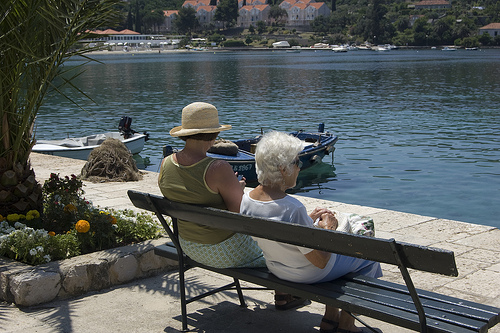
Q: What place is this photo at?
A: It is at the lake.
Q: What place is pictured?
A: It is a lake.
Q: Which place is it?
A: It is a lake.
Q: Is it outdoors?
A: Yes, it is outdoors.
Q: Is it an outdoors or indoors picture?
A: It is outdoors.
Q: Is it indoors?
A: No, it is outdoors.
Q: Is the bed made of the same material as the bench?
A: No, the bed is made of cement and the bench is made of wood.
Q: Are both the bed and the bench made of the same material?
A: No, the bed is made of cement and the bench is made of wood.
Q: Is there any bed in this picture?
A: Yes, there is a bed.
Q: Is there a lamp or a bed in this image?
A: Yes, there is a bed.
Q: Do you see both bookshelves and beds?
A: No, there is a bed but no bookshelves.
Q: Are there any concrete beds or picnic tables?
A: Yes, there is a concrete bed.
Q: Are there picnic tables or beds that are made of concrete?
A: Yes, the bed is made of concrete.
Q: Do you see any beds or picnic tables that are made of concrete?
A: Yes, the bed is made of concrete.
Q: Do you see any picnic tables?
A: No, there are no picnic tables.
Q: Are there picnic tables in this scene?
A: No, there are no picnic tables.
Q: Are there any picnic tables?
A: No, there are no picnic tables.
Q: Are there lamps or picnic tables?
A: No, there are no picnic tables or lamps.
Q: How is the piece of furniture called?
A: The piece of furniture is a bed.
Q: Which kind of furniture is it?
A: The piece of furniture is a bed.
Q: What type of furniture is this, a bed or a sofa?
A: That is a bed.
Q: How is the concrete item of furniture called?
A: The piece of furniture is a bed.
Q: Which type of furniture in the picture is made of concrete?
A: The furniture is a bed.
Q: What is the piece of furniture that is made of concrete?
A: The piece of furniture is a bed.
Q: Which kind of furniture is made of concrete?
A: The furniture is a bed.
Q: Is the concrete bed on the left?
A: Yes, the bed is on the left of the image.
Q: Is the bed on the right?
A: No, the bed is on the left of the image.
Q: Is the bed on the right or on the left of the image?
A: The bed is on the left of the image.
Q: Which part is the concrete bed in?
A: The bed is on the left of the image.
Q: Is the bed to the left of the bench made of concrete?
A: Yes, the bed is made of concrete.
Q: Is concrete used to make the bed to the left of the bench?
A: Yes, the bed is made of concrete.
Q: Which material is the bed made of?
A: The bed is made of cement.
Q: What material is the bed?
A: The bed is made of cement.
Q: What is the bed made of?
A: The bed is made of concrete.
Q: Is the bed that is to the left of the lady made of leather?
A: No, the bed is made of cement.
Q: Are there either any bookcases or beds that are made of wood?
A: No, there is a bed but it is made of concrete.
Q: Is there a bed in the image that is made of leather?
A: No, there is a bed but it is made of cement.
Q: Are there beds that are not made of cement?
A: No, there is a bed but it is made of cement.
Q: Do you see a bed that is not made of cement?
A: No, there is a bed but it is made of cement.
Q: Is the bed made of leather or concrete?
A: The bed is made of concrete.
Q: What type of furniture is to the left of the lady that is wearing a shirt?
A: The piece of furniture is a bed.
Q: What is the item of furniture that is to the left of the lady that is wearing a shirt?
A: The piece of furniture is a bed.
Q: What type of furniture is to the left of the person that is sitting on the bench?
A: The piece of furniture is a bed.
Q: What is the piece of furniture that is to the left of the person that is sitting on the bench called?
A: The piece of furniture is a bed.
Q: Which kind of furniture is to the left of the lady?
A: The piece of furniture is a bed.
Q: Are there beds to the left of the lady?
A: Yes, there is a bed to the left of the lady.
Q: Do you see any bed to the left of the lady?
A: Yes, there is a bed to the left of the lady.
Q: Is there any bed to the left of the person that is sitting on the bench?
A: Yes, there is a bed to the left of the lady.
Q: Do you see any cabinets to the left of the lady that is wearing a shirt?
A: No, there is a bed to the left of the lady.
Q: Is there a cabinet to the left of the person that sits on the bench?
A: No, there is a bed to the left of the lady.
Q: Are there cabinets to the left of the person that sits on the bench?
A: No, there is a bed to the left of the lady.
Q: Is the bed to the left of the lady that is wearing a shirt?
A: Yes, the bed is to the left of the lady.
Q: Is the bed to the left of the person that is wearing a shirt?
A: Yes, the bed is to the left of the lady.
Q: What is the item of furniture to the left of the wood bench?
A: The piece of furniture is a bed.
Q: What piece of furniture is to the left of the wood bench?
A: The piece of furniture is a bed.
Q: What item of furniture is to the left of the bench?
A: The piece of furniture is a bed.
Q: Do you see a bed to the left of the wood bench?
A: Yes, there is a bed to the left of the bench.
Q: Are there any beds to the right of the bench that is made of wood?
A: No, the bed is to the left of the bench.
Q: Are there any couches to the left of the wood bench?
A: No, there is a bed to the left of the bench.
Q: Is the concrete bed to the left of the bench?
A: Yes, the bed is to the left of the bench.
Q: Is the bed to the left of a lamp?
A: No, the bed is to the left of the bench.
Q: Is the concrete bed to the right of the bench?
A: No, the bed is to the left of the bench.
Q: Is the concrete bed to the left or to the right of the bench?
A: The bed is to the left of the bench.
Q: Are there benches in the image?
A: Yes, there is a bench.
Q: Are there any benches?
A: Yes, there is a bench.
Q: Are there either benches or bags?
A: Yes, there is a bench.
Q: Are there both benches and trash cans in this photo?
A: No, there is a bench but no trash cans.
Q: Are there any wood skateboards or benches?
A: Yes, there is a wood bench.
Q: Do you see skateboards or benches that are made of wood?
A: Yes, the bench is made of wood.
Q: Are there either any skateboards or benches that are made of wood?
A: Yes, the bench is made of wood.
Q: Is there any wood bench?
A: Yes, there is a bench that is made of wood.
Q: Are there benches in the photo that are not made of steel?
A: Yes, there is a bench that is made of wood.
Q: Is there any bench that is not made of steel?
A: Yes, there is a bench that is made of wood.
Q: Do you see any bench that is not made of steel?
A: Yes, there is a bench that is made of wood.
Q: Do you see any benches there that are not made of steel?
A: Yes, there is a bench that is made of wood.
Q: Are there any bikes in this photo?
A: No, there are no bikes.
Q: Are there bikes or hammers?
A: No, there are no bikes or hammers.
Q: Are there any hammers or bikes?
A: No, there are no bikes or hammers.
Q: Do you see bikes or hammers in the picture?
A: No, there are no bikes or hammers.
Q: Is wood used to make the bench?
A: Yes, the bench is made of wood.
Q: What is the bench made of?
A: The bench is made of wood.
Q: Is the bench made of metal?
A: No, the bench is made of wood.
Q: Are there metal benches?
A: No, there is a bench but it is made of wood.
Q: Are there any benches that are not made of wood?
A: No, there is a bench but it is made of wood.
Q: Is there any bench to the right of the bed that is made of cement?
A: Yes, there is a bench to the right of the bed.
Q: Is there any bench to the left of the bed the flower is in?
A: No, the bench is to the right of the bed.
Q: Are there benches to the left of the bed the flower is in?
A: No, the bench is to the right of the bed.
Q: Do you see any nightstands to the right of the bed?
A: No, there is a bench to the right of the bed.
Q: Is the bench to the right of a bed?
A: Yes, the bench is to the right of a bed.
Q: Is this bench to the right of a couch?
A: No, the bench is to the right of a bed.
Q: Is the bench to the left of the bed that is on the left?
A: No, the bench is to the right of the bed.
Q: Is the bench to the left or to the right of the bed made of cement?
A: The bench is to the right of the bed.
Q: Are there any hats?
A: Yes, there is a hat.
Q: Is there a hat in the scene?
A: Yes, there is a hat.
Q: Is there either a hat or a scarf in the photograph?
A: Yes, there is a hat.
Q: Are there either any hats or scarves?
A: Yes, there is a hat.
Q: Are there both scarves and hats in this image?
A: No, there is a hat but no scarves.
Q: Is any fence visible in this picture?
A: No, there are no fences.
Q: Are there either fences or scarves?
A: No, there are no fences or scarves.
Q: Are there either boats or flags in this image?
A: Yes, there is a boat.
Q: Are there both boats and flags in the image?
A: No, there is a boat but no flags.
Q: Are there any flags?
A: No, there are no flags.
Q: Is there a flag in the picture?
A: No, there are no flags.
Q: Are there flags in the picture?
A: No, there are no flags.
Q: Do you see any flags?
A: No, there are no flags.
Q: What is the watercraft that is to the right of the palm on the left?
A: The watercraft is a boat.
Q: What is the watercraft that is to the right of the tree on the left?
A: The watercraft is a boat.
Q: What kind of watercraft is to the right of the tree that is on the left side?
A: The watercraft is a boat.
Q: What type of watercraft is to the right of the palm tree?
A: The watercraft is a boat.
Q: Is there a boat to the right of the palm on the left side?
A: Yes, there is a boat to the right of the palm.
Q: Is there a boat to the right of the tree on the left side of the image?
A: Yes, there is a boat to the right of the palm.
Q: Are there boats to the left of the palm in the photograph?
A: No, the boat is to the right of the palm.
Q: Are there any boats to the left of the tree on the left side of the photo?
A: No, the boat is to the right of the palm.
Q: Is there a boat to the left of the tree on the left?
A: No, the boat is to the right of the palm.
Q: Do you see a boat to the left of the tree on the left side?
A: No, the boat is to the right of the palm.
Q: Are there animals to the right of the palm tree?
A: No, there is a boat to the right of the palm tree.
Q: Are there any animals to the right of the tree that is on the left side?
A: No, there is a boat to the right of the palm tree.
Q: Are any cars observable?
A: No, there are no cars.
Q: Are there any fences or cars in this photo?
A: No, there are no cars or fences.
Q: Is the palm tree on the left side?
A: Yes, the palm tree is on the left of the image.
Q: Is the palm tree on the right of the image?
A: No, the palm tree is on the left of the image.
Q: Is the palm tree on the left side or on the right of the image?
A: The palm tree is on the left of the image.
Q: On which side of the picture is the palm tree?
A: The palm tree is on the left of the image.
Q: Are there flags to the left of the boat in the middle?
A: No, there is a palm tree to the left of the boat.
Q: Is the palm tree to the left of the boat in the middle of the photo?
A: Yes, the palm tree is to the left of the boat.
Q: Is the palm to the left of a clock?
A: No, the palm is to the left of the boat.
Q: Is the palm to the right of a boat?
A: No, the palm is to the left of a boat.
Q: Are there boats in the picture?
A: Yes, there is a boat.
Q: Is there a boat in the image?
A: Yes, there is a boat.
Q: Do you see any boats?
A: Yes, there is a boat.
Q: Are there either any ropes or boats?
A: Yes, there is a boat.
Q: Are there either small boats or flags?
A: Yes, there is a small boat.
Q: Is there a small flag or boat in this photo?
A: Yes, there is a small boat.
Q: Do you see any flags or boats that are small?
A: Yes, the boat is small.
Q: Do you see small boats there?
A: Yes, there is a small boat.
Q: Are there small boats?
A: Yes, there is a small boat.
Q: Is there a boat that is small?
A: Yes, there is a boat that is small.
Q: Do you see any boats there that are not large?
A: Yes, there is a small boat.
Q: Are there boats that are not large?
A: Yes, there is a small boat.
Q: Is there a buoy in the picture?
A: No, there are no buoys.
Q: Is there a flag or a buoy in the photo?
A: No, there are no buoys or flags.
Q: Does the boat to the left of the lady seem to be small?
A: Yes, the boat is small.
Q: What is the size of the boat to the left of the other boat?
A: The boat is small.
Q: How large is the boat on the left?
A: The boat is small.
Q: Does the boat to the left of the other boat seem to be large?
A: No, the boat is small.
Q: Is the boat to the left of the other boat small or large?
A: The boat is small.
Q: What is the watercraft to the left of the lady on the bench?
A: The watercraft is a boat.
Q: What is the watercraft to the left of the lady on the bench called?
A: The watercraft is a boat.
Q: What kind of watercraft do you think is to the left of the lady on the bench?
A: The watercraft is a boat.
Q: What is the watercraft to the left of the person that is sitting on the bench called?
A: The watercraft is a boat.